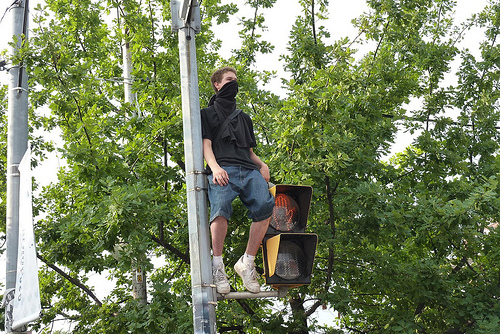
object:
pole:
[175, 35, 218, 333]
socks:
[206, 254, 258, 266]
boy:
[198, 69, 276, 295]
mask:
[217, 81, 241, 102]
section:
[316, 11, 460, 221]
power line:
[256, 92, 498, 131]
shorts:
[203, 166, 274, 225]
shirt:
[198, 103, 258, 171]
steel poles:
[4, 2, 217, 333]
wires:
[16, 47, 480, 160]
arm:
[202, 108, 230, 187]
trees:
[5, 0, 485, 331]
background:
[0, 2, 496, 332]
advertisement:
[5, 148, 44, 329]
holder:
[260, 181, 313, 286]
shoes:
[210, 255, 263, 295]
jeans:
[205, 166, 276, 222]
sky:
[303, 2, 383, 56]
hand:
[266, 193, 296, 234]